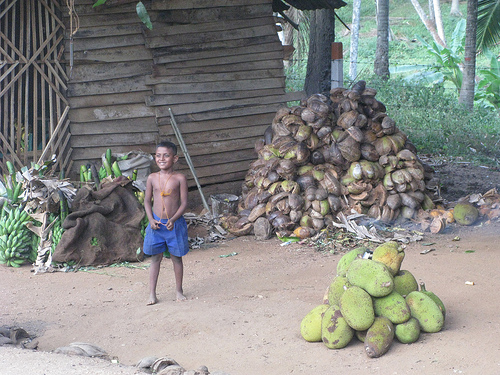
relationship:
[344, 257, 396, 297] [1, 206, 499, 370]
fruits are on ground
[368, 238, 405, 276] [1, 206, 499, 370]
fruits are on ground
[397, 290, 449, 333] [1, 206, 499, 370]
fruits are on ground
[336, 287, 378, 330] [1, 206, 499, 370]
fruits are on ground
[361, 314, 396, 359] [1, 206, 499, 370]
fruits are on ground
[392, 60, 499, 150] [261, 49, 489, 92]
plants on background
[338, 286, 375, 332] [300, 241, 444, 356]
fruits on pile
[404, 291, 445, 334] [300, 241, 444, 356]
fruits on pile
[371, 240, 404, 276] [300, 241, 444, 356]
fruits on pile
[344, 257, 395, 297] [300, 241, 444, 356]
fruits on pile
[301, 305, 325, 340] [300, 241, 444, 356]
melon on pile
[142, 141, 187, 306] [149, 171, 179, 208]
boy has bare chest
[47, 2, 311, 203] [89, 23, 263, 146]
wood form stack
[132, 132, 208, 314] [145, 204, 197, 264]
boy in shorts